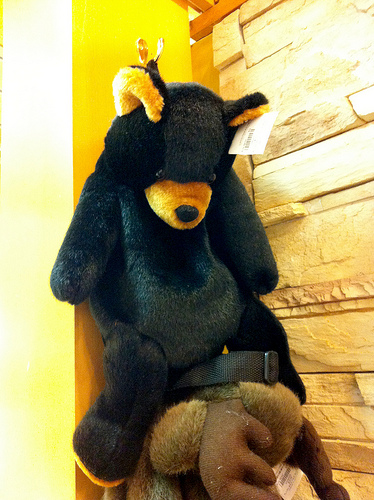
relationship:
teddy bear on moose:
[49, 66, 306, 485] [118, 382, 350, 497]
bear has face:
[49, 56, 308, 487] [128, 122, 232, 230]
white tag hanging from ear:
[245, 115, 274, 148] [223, 91, 274, 127]